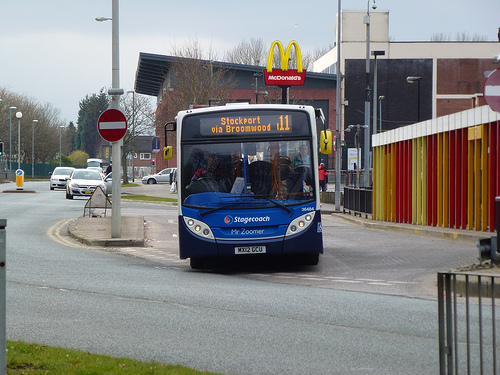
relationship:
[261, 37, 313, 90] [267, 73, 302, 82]
sign reads mcdonald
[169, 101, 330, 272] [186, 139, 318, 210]
bus has windshield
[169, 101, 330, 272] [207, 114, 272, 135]
bus reads stockport via broomw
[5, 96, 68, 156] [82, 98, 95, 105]
trees without leaves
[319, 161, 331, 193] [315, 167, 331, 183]
person ears jacket